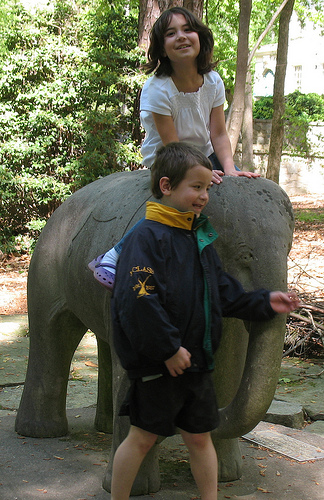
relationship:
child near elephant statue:
[115, 144, 301, 493] [15, 169, 294, 452]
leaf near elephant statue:
[52, 453, 64, 461] [15, 169, 294, 452]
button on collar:
[207, 232, 215, 239] [145, 199, 221, 254]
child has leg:
[115, 144, 301, 493] [108, 369, 179, 498]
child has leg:
[115, 144, 301, 493] [176, 369, 221, 500]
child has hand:
[115, 144, 301, 493] [128, 299, 193, 378]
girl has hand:
[87, 9, 260, 288] [211, 130, 262, 179]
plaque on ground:
[242, 430, 324, 462] [0, 310, 322, 497]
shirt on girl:
[139, 71, 226, 169] [135, 41, 268, 185]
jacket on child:
[110, 200, 272, 375] [110, 142, 301, 498]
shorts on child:
[118, 361, 221, 436] [110, 142, 301, 498]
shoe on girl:
[87, 252, 116, 290] [85, 51, 264, 296]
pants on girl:
[99, 147, 248, 262] [87, 9, 260, 288]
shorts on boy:
[118, 361, 221, 436] [77, 127, 301, 500]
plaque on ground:
[242, 430, 324, 462] [0, 242, 320, 500]